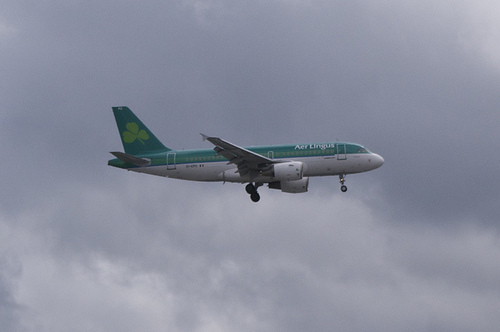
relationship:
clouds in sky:
[35, 212, 165, 329] [69, 16, 383, 87]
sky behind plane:
[69, 16, 383, 87] [91, 78, 396, 211]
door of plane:
[333, 141, 350, 168] [91, 78, 396, 211]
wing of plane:
[195, 124, 272, 177] [91, 78, 396, 211]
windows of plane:
[274, 148, 339, 160] [91, 78, 396, 211]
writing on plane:
[289, 141, 338, 152] [91, 78, 396, 211]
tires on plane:
[336, 179, 352, 195] [91, 78, 396, 211]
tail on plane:
[106, 102, 164, 152] [91, 78, 396, 211]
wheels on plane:
[236, 176, 272, 206] [91, 78, 396, 211]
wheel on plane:
[336, 179, 352, 195] [91, 78, 396, 211]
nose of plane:
[367, 143, 389, 176] [91, 78, 396, 211]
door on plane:
[333, 141, 350, 168] [91, 78, 396, 211]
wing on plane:
[195, 124, 272, 177] [91, 78, 396, 211]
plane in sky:
[91, 78, 396, 211] [69, 16, 383, 87]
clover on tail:
[119, 115, 152, 149] [106, 102, 164, 152]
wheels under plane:
[236, 176, 272, 206] [91, 78, 396, 211]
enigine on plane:
[269, 157, 311, 181] [91, 78, 396, 211]